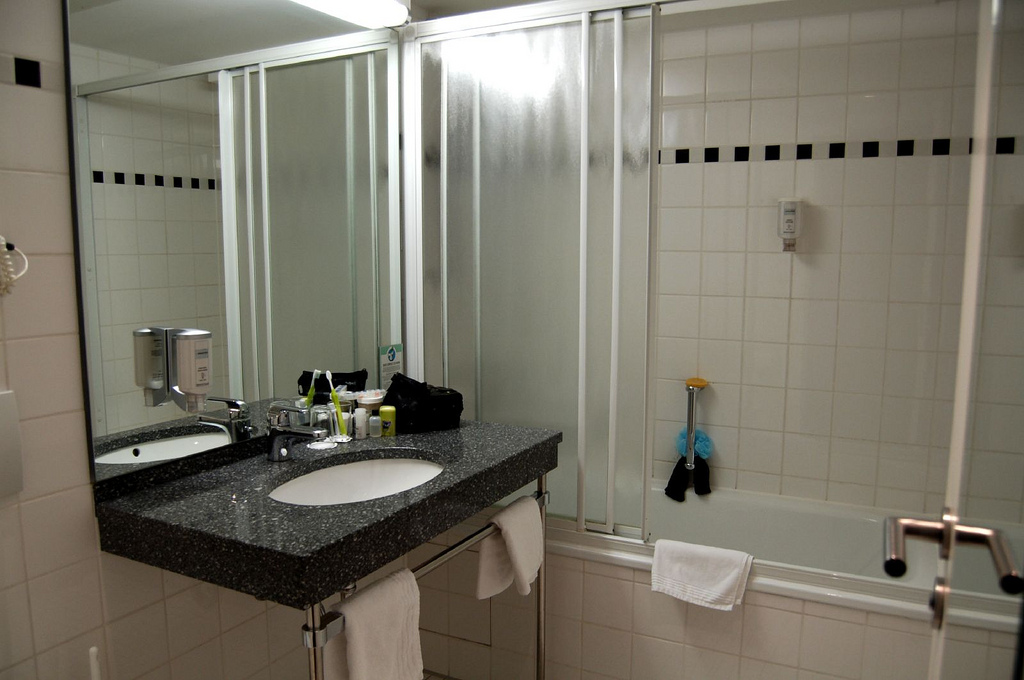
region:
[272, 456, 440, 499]
white and round sink bowl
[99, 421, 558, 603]
black sink counter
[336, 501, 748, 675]
three white towels hanged up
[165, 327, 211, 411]
white and silver soap dispenser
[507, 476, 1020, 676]
white bathtub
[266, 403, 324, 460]
silver faucet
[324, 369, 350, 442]
yellow toothbrush in a clear cup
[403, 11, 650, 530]
clear sliding doors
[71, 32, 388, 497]
mirror reflection of clear sliding doors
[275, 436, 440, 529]
white sink basin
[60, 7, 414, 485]
mirror above the sink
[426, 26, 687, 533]
doors on the shower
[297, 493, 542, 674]
hand towels hanging from silver bar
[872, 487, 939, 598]
silver handle on the door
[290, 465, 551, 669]
silver poles supporting the countertop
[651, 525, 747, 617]
white towel draped over the bathtub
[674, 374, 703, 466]
rail on the shower wall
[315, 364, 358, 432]
toothbrush on the countertop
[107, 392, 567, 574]
The granite counter top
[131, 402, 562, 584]
A granite counter top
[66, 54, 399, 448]
The mirror above the sink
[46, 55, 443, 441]
A mirror above the sink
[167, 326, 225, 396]
The soap dispenser on the mirror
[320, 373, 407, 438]
The personal items on the counter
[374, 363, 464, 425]
A black cosmetic bag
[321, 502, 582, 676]
The two towels under the sink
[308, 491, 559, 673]
A set of towels under the sink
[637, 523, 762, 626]
The towel hanging over the bath tub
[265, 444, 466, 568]
white sink in bathroom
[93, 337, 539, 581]
black and white counter around sink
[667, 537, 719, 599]
white cloth on tub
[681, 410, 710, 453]
blue puff in tub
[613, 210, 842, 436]
white tile tub wall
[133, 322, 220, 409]
soap dispenser on mirror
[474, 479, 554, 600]
white towel on bar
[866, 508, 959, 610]
white handle on door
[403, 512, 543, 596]
metal bar with towels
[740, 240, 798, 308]
white tile on the bathroom wall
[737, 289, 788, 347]
white tile on the bathroom wall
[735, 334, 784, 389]
white tile on the bathroom wall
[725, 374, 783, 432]
white tile on the bathroom wall